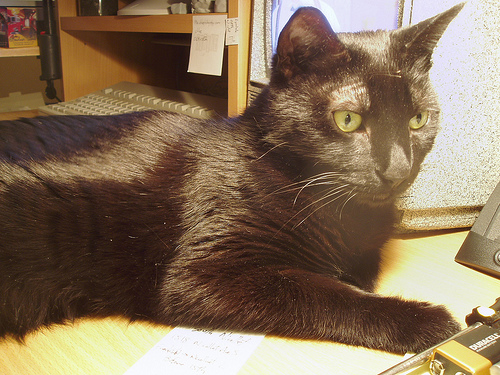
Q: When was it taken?
A: During daytime.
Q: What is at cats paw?
A: Battery.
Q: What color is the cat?
A: Black.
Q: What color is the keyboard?
A: Gray.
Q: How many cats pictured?
A: One.